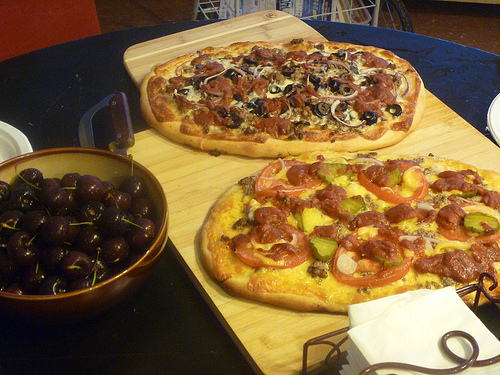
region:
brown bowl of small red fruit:
[0, 146, 171, 319]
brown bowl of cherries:
[2, 146, 172, 318]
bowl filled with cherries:
[0, 144, 172, 320]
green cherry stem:
[120, 216, 147, 231]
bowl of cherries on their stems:
[0, 144, 172, 316]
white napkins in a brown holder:
[302, 271, 499, 374]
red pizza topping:
[386, 201, 418, 223]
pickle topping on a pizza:
[307, 233, 339, 260]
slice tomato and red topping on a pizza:
[234, 224, 311, 268]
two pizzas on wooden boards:
[139, 37, 499, 374]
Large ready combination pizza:
[141, 39, 431, 159]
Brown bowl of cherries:
[0, 146, 173, 329]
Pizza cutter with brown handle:
[74, 88, 136, 166]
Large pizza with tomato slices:
[199, 152, 494, 314]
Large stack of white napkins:
[335, 291, 499, 374]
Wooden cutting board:
[121, 2, 337, 88]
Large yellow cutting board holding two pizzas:
[108, 72, 499, 368]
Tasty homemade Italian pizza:
[137, 33, 432, 154]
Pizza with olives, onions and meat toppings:
[143, 39, 430, 157]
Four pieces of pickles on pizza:
[312, 155, 498, 267]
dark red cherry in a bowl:
[118, 211, 159, 245]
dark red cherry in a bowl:
[100, 233, 134, 264]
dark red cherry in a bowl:
[57, 247, 97, 287]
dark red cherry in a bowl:
[42, 210, 71, 246]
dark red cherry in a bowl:
[69, 168, 104, 206]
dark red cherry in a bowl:
[39, 184, 71, 210]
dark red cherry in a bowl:
[15, 162, 45, 186]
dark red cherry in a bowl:
[10, 184, 37, 214]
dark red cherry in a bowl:
[7, 228, 44, 265]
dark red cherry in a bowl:
[119, 151, 146, 201]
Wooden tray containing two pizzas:
[107, 9, 499, 372]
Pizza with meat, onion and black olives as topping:
[140, 39, 425, 152]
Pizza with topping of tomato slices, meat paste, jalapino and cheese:
[201, 153, 498, 311]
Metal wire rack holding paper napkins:
[304, 273, 499, 373]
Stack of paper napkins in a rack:
[338, 285, 498, 374]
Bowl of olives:
[0, 145, 165, 314]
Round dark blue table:
[0, 16, 498, 371]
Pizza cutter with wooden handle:
[77, 93, 132, 155]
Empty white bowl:
[0, 121, 35, 164]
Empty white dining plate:
[487, 93, 499, 145]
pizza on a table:
[127, 30, 497, 320]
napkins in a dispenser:
[328, 283, 490, 367]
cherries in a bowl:
[5, 143, 177, 308]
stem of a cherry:
[83, 267, 102, 289]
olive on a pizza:
[356, 105, 378, 127]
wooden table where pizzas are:
[234, 308, 312, 355]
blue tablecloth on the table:
[433, 40, 497, 101]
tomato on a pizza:
[253, 159, 284, 203]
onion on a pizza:
[330, 98, 352, 128]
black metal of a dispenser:
[423, 320, 494, 367]